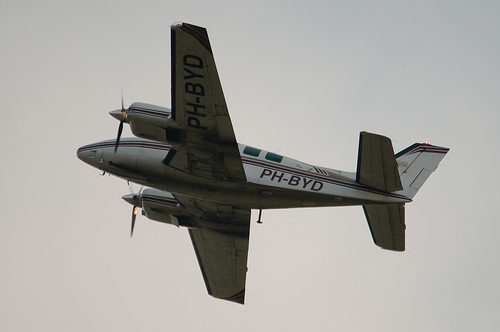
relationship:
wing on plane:
[350, 128, 407, 198] [73, 15, 451, 310]